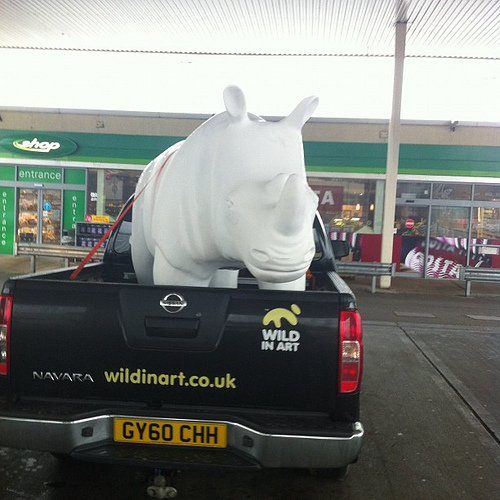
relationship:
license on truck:
[113, 417, 229, 448] [0, 190, 366, 495]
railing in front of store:
[11, 239, 107, 275] [3, 102, 500, 283]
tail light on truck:
[340, 311, 364, 396] [0, 190, 366, 495]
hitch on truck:
[145, 471, 180, 496] [0, 190, 366, 495]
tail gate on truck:
[6, 276, 343, 422] [0, 190, 366, 495]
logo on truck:
[260, 300, 302, 353] [0, 190, 366, 495]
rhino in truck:
[128, 84, 322, 289] [0, 190, 366, 495]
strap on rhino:
[68, 150, 175, 283] [128, 84, 322, 289]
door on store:
[12, 181, 65, 251] [3, 102, 500, 283]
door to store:
[12, 181, 65, 251] [3, 102, 500, 283]